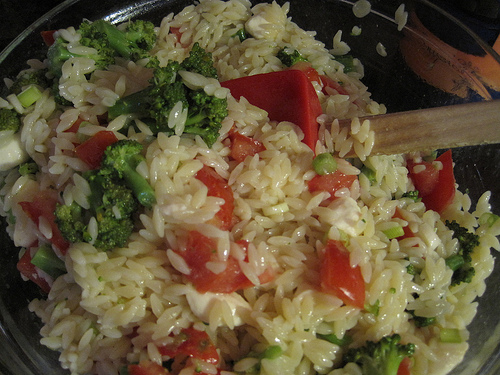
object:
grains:
[213, 230, 230, 262]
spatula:
[215, 67, 499, 164]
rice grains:
[238, 260, 261, 286]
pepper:
[192, 158, 236, 233]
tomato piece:
[226, 130, 266, 165]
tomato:
[313, 239, 368, 308]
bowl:
[0, 0, 500, 375]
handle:
[325, 99, 500, 162]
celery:
[12, 82, 41, 108]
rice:
[0, 0, 500, 375]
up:
[0, 1, 500, 375]